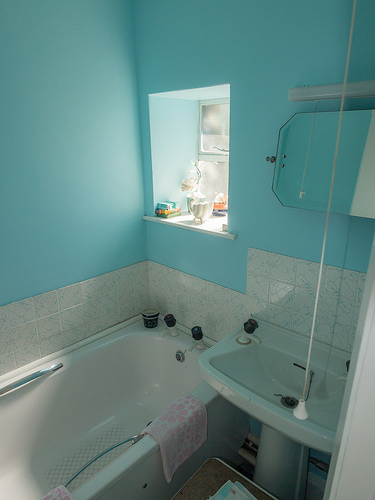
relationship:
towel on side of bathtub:
[141, 394, 207, 483] [7, 309, 252, 499]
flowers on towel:
[161, 407, 199, 447] [141, 394, 207, 483]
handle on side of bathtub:
[0, 361, 63, 397] [7, 309, 252, 499]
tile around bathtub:
[5, 248, 361, 358] [7, 309, 252, 499]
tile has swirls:
[5, 248, 361, 358] [52, 299, 94, 326]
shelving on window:
[132, 194, 239, 249] [138, 75, 255, 241]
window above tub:
[138, 75, 255, 241] [5, 309, 259, 493]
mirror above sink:
[260, 99, 372, 225] [197, 315, 353, 497]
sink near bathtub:
[197, 315, 353, 497] [7, 309, 252, 499]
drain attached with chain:
[280, 395, 299, 409] [279, 365, 319, 407]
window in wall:
[148, 84, 230, 234] [133, 3, 373, 303]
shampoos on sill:
[150, 193, 224, 228] [140, 202, 234, 244]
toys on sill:
[149, 193, 232, 231] [140, 202, 234, 244]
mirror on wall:
[197, 98, 229, 154] [133, 3, 373, 303]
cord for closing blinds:
[294, 0, 359, 420] [296, 5, 364, 439]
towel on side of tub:
[141, 394, 207, 483] [5, 309, 259, 493]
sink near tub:
[195, 311, 362, 497] [5, 309, 259, 493]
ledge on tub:
[42, 420, 133, 492] [5, 309, 259, 493]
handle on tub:
[0, 361, 63, 397] [5, 309, 259, 493]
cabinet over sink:
[266, 114, 364, 222] [195, 311, 362, 497]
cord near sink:
[296, 3, 354, 431] [195, 311, 362, 497]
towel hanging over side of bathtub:
[141, 394, 207, 483] [0, 313, 251, 499]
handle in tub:
[0, 361, 63, 397] [4, 296, 254, 498]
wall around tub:
[3, 248, 249, 372] [5, 309, 259, 493]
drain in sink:
[280, 395, 299, 409] [197, 315, 353, 497]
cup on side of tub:
[136, 305, 163, 334] [5, 309, 259, 493]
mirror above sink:
[197, 98, 229, 154] [197, 315, 353, 497]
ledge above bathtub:
[143, 206, 237, 240] [7, 309, 252, 499]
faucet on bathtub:
[159, 313, 179, 338] [7, 309, 252, 499]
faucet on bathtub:
[186, 325, 207, 352] [7, 309, 252, 499]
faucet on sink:
[237, 317, 262, 344] [197, 315, 353, 497]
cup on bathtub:
[142, 307, 160, 329] [7, 309, 252, 499]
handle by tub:
[63, 432, 144, 488] [5, 309, 259, 493]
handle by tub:
[0, 361, 63, 397] [5, 309, 259, 493]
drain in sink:
[280, 395, 299, 409] [195, 311, 362, 497]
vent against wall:
[238, 433, 267, 468] [132, 4, 373, 498]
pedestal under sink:
[250, 415, 318, 498] [195, 317, 367, 464]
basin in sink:
[215, 342, 356, 445] [195, 317, 367, 464]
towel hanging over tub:
[140, 393, 216, 480] [5, 309, 259, 493]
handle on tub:
[1, 356, 68, 394] [5, 309, 259, 493]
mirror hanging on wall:
[197, 98, 229, 154] [136, 6, 371, 404]